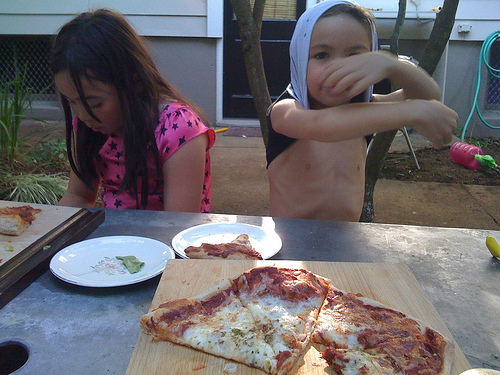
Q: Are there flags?
A: No, there are no flags.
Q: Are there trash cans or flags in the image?
A: No, there are no flags or trash cans.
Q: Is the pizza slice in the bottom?
A: Yes, the pizza slice is in the bottom of the image.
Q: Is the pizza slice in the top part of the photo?
A: No, the pizza slice is in the bottom of the image.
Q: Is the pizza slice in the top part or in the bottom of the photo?
A: The pizza slice is in the bottom of the image.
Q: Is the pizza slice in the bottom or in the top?
A: The pizza slice is in the bottom of the image.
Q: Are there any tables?
A: Yes, there is a table.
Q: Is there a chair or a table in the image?
A: Yes, there is a table.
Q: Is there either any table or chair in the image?
A: Yes, there is a table.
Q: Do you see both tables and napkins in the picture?
A: No, there is a table but no napkins.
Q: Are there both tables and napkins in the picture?
A: No, there is a table but no napkins.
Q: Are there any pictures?
A: No, there are no pictures.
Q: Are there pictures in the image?
A: No, there are no pictures.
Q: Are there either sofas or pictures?
A: No, there are no pictures or sofas.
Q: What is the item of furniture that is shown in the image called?
A: The piece of furniture is a table.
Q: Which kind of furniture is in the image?
A: The furniture is a table.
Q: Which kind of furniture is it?
A: The piece of furniture is a table.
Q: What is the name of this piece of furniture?
A: This is a table.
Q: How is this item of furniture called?
A: This is a table.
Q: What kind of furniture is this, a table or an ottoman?
A: This is a table.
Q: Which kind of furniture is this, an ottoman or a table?
A: This is a table.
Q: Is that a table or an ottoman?
A: That is a table.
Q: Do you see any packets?
A: No, there are no packets.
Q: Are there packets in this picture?
A: No, there are no packets.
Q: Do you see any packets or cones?
A: No, there are no packets or cones.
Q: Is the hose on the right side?
A: Yes, the hose is on the right of the image.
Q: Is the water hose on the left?
A: No, the water hose is on the right of the image.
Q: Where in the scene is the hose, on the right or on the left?
A: The hose is on the right of the image.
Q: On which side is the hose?
A: The hose is on the right of the image.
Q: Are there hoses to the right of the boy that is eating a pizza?
A: Yes, there is a hose to the right of the boy.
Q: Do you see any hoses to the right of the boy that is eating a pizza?
A: Yes, there is a hose to the right of the boy.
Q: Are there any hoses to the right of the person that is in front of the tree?
A: Yes, there is a hose to the right of the boy.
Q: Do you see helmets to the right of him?
A: No, there is a hose to the right of the boy.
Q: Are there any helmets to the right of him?
A: No, there is a hose to the right of the boy.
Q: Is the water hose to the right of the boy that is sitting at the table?
A: Yes, the water hose is to the right of the boy.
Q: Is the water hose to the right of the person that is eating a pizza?
A: Yes, the water hose is to the right of the boy.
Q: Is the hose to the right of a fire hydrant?
A: No, the hose is to the right of the boy.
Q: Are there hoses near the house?
A: Yes, there is a hose near the house.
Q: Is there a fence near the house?
A: No, there is a hose near the house.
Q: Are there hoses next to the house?
A: Yes, there is a hose next to the house.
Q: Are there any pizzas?
A: Yes, there is a pizza.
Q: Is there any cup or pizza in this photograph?
A: Yes, there is a pizza.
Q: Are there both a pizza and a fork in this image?
A: No, there is a pizza but no forks.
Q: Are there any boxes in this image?
A: No, there are no boxes.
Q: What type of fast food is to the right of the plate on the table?
A: The food is a pizza.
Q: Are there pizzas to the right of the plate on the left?
A: Yes, there is a pizza to the right of the plate.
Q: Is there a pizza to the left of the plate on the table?
A: No, the pizza is to the right of the plate.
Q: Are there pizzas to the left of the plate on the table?
A: No, the pizza is to the right of the plate.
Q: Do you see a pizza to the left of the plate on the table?
A: No, the pizza is to the right of the plate.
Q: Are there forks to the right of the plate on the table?
A: No, there is a pizza to the right of the plate.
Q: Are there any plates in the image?
A: Yes, there is a plate.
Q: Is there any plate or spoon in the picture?
A: Yes, there is a plate.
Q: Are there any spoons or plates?
A: Yes, there is a plate.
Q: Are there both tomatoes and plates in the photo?
A: No, there is a plate but no tomatoes.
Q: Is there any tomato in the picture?
A: No, there are no tomatoes.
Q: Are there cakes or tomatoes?
A: No, there are no tomatoes or cakes.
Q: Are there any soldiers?
A: No, there are no soldiers.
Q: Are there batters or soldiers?
A: No, there are no soldiers or batters.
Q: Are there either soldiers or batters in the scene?
A: No, there are no soldiers or batters.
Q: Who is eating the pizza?
A: The boy is eating the pizza.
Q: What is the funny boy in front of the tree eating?
A: The boy is eating a pizza.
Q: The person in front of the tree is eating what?
A: The boy is eating a pizza.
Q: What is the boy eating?
A: The boy is eating a pizza.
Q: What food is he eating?
A: The boy is eating a pizza.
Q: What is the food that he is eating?
A: The food is a pizza.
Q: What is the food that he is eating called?
A: The food is a pizza.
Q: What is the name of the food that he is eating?
A: The food is a pizza.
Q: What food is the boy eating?
A: The boy is eating a pizza.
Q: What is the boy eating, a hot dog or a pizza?
A: The boy is eating a pizza.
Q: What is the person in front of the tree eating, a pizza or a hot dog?
A: The boy is eating a pizza.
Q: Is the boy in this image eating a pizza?
A: Yes, the boy is eating a pizza.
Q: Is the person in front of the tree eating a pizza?
A: Yes, the boy is eating a pizza.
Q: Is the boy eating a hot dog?
A: No, the boy is eating a pizza.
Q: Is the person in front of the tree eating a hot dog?
A: No, the boy is eating a pizza.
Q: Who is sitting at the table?
A: The boy is sitting at the table.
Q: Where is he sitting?
A: The boy is sitting at the table.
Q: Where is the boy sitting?
A: The boy is sitting at the table.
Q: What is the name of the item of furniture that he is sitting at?
A: The piece of furniture is a table.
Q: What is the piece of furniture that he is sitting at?
A: The piece of furniture is a table.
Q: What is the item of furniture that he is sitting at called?
A: The piece of furniture is a table.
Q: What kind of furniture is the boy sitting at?
A: The boy is sitting at the table.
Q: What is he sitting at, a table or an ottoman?
A: The boy is sitting at a table.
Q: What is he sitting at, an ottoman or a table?
A: The boy is sitting at a table.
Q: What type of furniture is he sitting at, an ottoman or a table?
A: The boy is sitting at a table.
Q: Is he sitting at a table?
A: Yes, the boy is sitting at a table.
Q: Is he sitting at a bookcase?
A: No, the boy is sitting at a table.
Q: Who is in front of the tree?
A: The boy is in front of the tree.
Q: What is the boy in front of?
A: The boy is in front of the tree.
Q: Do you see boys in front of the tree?
A: Yes, there is a boy in front of the tree.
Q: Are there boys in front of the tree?
A: Yes, there is a boy in front of the tree.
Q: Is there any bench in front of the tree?
A: No, there is a boy in front of the tree.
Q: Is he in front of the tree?
A: Yes, the boy is in front of the tree.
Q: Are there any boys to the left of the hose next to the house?
A: Yes, there is a boy to the left of the hose.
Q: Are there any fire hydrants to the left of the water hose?
A: No, there is a boy to the left of the water hose.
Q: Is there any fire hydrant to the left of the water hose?
A: No, there is a boy to the left of the water hose.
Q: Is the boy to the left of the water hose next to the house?
A: Yes, the boy is to the left of the water hose.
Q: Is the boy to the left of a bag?
A: No, the boy is to the left of the water hose.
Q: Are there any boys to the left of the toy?
A: Yes, there is a boy to the left of the toy.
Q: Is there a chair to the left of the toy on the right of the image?
A: No, there is a boy to the left of the toy.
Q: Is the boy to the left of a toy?
A: Yes, the boy is to the left of a toy.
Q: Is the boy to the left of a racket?
A: No, the boy is to the left of a toy.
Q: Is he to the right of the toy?
A: No, the boy is to the left of the toy.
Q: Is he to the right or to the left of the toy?
A: The boy is to the left of the toy.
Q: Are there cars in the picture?
A: No, there are no cars.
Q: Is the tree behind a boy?
A: Yes, the tree is behind a boy.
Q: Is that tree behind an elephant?
A: No, the tree is behind a boy.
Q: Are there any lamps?
A: No, there are no lamps.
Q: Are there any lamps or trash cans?
A: No, there are no lamps or trash cans.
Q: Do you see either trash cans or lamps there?
A: No, there are no lamps or trash cans.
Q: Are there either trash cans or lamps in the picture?
A: No, there are no lamps or trash cans.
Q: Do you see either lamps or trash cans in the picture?
A: No, there are no lamps or trash cans.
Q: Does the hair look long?
A: Yes, the hair is long.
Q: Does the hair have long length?
A: Yes, the hair is long.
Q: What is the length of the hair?
A: The hair is long.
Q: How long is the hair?
A: The hair is long.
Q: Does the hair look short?
A: No, the hair is long.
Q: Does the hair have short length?
A: No, the hair is long.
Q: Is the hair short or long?
A: The hair is long.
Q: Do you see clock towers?
A: No, there are no clock towers.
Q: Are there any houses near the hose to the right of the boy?
A: Yes, there is a house near the water hose.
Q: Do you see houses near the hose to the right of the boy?
A: Yes, there is a house near the water hose.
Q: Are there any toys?
A: Yes, there is a toy.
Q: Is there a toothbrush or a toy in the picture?
A: Yes, there is a toy.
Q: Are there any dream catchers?
A: No, there are no dream catchers.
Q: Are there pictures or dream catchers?
A: No, there are no dream catchers or pictures.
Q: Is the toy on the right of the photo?
A: Yes, the toy is on the right of the image.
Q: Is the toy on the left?
A: No, the toy is on the right of the image.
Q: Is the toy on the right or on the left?
A: The toy is on the right of the image.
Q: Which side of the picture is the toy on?
A: The toy is on the right of the image.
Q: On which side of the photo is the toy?
A: The toy is on the right of the image.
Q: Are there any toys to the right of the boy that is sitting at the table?
A: Yes, there is a toy to the right of the boy.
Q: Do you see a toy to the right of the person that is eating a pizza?
A: Yes, there is a toy to the right of the boy.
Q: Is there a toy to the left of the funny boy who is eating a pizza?
A: No, the toy is to the right of the boy.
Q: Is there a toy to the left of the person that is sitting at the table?
A: No, the toy is to the right of the boy.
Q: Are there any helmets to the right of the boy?
A: No, there is a toy to the right of the boy.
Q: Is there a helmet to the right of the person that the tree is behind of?
A: No, there is a toy to the right of the boy.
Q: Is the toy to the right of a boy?
A: Yes, the toy is to the right of a boy.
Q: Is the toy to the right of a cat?
A: No, the toy is to the right of a boy.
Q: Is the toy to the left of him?
A: No, the toy is to the right of the boy.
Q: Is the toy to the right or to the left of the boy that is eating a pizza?
A: The toy is to the right of the boy.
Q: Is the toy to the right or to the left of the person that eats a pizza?
A: The toy is to the right of the boy.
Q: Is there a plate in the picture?
A: Yes, there is a plate.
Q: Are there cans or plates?
A: Yes, there is a plate.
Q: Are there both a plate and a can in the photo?
A: No, there is a plate but no cans.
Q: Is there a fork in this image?
A: No, there are no forks.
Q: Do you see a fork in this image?
A: No, there are no forks.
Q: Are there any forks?
A: No, there are no forks.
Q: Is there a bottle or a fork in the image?
A: No, there are no forks or bottles.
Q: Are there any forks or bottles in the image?
A: No, there are no forks or bottles.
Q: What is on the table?
A: The plate is on the table.